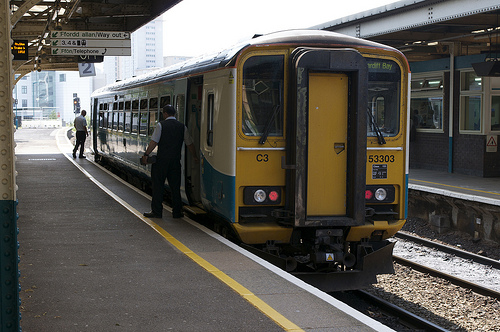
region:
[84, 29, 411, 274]
yellow train engine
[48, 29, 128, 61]
white sign with green arrows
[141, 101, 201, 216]
man wearing conductor's uniform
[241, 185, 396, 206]
headlights set in black mold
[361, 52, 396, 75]
train destination display in green letters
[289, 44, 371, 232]
large rectangular rubber bumper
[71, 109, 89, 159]
man wearing white shirt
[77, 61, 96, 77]
white sign with the number 2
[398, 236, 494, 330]
rocks and gravel in between train tracks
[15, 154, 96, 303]
grey train platform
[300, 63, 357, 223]
yellow door on train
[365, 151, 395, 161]
numbers on the train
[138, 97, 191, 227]
man standing outside the train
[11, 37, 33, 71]
lighted sign on the building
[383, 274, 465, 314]
gravel on the train tracks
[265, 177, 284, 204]
red light non the train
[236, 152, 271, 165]
writting on the train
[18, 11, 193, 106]
building in the background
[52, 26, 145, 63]
signs hanging from building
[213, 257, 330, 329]
yellow and white line on pavement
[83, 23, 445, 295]
a yellow train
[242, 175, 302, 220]
the left headlight of the train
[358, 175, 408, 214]
the right headlight of the train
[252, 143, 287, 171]
the letter and number combination C3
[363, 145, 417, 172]
the numbers 53303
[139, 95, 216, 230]
a man getting ready to board a train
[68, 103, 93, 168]
a man standing at the back of the train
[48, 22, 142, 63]
the sign showing where the train station is located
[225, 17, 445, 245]
the front of the train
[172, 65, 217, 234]
the door to enter the train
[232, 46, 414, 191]
this is a train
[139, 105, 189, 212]
this is a man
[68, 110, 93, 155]
the man is walking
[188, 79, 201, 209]
this is a door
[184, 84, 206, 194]
the door is open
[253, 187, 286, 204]
the front light is off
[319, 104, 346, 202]
the front is yellow in color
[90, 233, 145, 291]
this is a road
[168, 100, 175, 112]
the man is bald headed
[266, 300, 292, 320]
yellow strip is on the road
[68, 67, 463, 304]
A train at a station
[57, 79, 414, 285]
A stopped train at a station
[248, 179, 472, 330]
Train tracks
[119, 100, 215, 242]
A man next to a train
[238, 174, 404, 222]
The headlights on a train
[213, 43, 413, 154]
The windshield on a train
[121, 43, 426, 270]
A yellow and white train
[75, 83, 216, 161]
The windows on a train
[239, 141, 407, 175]
Black letters and numbers on a train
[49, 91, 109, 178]
a person getting on a train